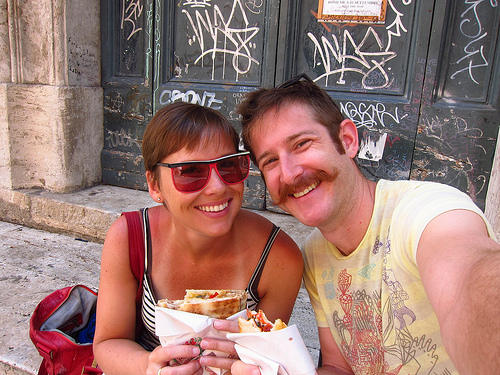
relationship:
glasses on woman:
[161, 164, 252, 188] [110, 81, 248, 367]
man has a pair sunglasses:
[234, 72, 500, 375] [247, 71, 317, 88]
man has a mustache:
[234, 72, 500, 375] [268, 169, 340, 206]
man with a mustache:
[241, 74, 484, 345] [271, 169, 340, 208]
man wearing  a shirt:
[234, 72, 500, 375] [300, 175, 463, 362]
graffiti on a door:
[155, 20, 433, 110] [163, 11, 429, 98]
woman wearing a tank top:
[92, 98, 306, 368] [137, 218, 284, 343]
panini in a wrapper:
[159, 286, 238, 313] [170, 285, 238, 308]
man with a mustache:
[234, 72, 500, 375] [274, 166, 339, 206]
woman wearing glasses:
[92, 98, 306, 368] [153, 151, 251, 194]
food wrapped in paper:
[151, 282, 292, 368] [154, 331, 301, 363]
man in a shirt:
[234, 72, 500, 375] [297, 179, 479, 368]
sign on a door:
[309, 4, 394, 31] [148, 9, 433, 115]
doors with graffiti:
[153, 9, 428, 101] [160, 10, 416, 91]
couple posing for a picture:
[84, 70, 453, 360] [15, 9, 485, 358]